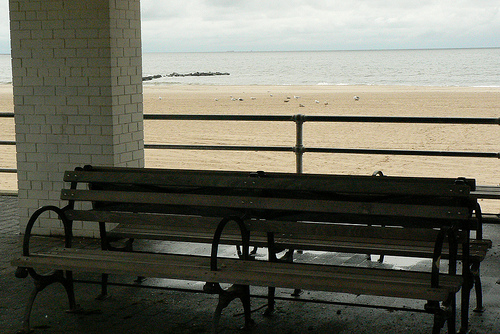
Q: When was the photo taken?
A: Afternoon.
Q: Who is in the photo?
A: No one.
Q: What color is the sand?
A: Brown.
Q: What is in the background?
A: Water.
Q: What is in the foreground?
A: A bench.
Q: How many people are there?
A: None.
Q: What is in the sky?
A: Clouds.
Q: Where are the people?
A: On a beach.